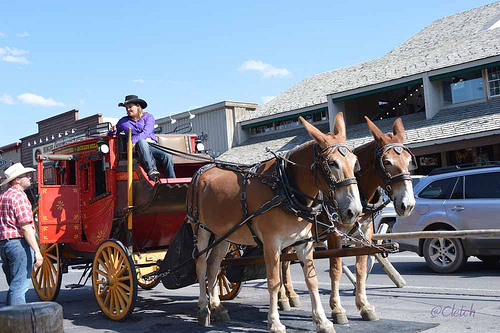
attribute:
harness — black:
[268, 159, 301, 225]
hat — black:
[112, 95, 147, 106]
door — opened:
[35, 151, 91, 243]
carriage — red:
[53, 190, 95, 222]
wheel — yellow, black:
[79, 232, 161, 330]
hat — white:
[7, 160, 42, 191]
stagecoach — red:
[33, 135, 208, 320]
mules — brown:
[211, 145, 266, 221]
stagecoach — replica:
[18, 121, 200, 307]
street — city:
[2, 260, 499, 332]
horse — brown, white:
[183, 120, 408, 330]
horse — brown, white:
[274, 116, 413, 323]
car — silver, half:
[384, 165, 498, 274]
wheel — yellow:
[91, 236, 149, 320]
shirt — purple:
[110, 113, 162, 145]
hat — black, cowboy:
[121, 95, 146, 107]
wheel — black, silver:
[81, 224, 150, 331]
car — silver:
[388, 157, 498, 271]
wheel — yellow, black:
[73, 230, 154, 324]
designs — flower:
[38, 188, 88, 243]